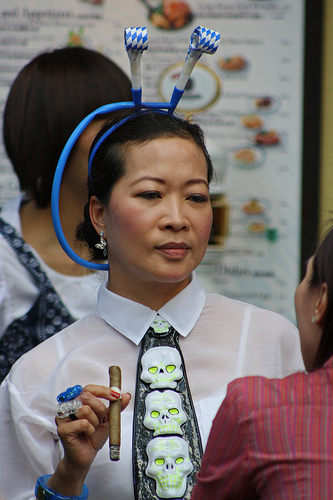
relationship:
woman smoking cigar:
[0, 109, 305, 497] [77, 369, 161, 459]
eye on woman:
[136, 183, 167, 207] [44, 131, 292, 382]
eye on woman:
[180, 169, 221, 222] [63, 159, 267, 381]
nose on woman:
[160, 202, 193, 232] [44, 131, 292, 382]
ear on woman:
[73, 187, 129, 247] [76, 124, 266, 402]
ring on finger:
[57, 389, 84, 412] [79, 390, 102, 423]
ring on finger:
[53, 398, 102, 417] [75, 394, 96, 424]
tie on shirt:
[133, 359, 214, 431] [205, 316, 258, 360]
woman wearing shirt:
[44, 131, 292, 382] [214, 312, 272, 354]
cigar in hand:
[102, 363, 125, 458] [37, 378, 124, 465]